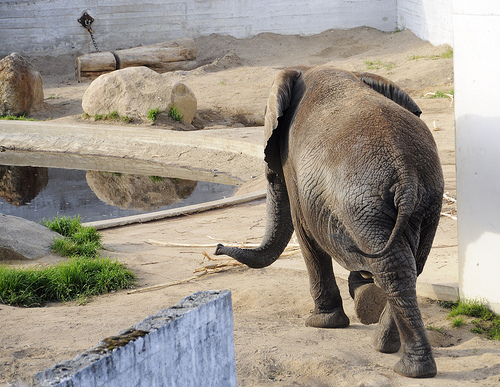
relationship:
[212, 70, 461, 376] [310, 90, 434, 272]
elephant has skin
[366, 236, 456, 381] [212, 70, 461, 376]
leg of elephant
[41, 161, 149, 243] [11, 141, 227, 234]
pond has water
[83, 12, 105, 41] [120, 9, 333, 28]
chain on wall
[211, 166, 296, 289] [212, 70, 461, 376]
trunk of elephant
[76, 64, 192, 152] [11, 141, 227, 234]
rock in water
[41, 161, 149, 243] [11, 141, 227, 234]
pond of water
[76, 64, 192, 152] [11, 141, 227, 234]
rock on water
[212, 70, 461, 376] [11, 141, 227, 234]
elephant by water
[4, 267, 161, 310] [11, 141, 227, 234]
grass by water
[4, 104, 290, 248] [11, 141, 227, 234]
pool of water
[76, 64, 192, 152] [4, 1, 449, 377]
rock in pen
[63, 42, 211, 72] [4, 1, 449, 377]
log in pen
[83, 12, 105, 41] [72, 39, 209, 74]
chain around a log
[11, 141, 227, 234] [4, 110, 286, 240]
water in pool